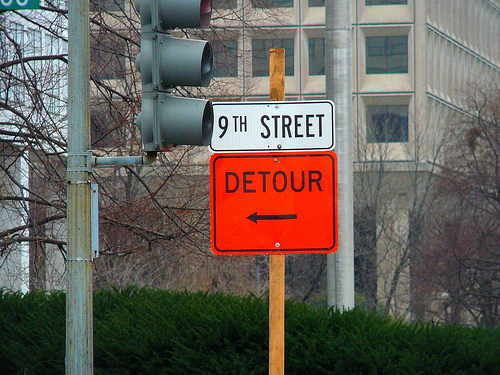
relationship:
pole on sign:
[267, 47, 284, 374] [208, 97, 335, 152]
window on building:
[366, 104, 408, 143] [87, 0, 499, 323]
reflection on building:
[365, 36, 405, 74] [220, 9, 492, 325]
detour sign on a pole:
[209, 150, 339, 255] [267, 47, 284, 374]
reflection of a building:
[365, 36, 405, 74] [15, 1, 475, 318]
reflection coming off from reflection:
[365, 36, 406, 73] [365, 36, 405, 74]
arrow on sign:
[245, 210, 301, 224] [204, 151, 342, 255]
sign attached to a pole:
[209, 99, 339, 155] [264, 40, 301, 375]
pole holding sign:
[267, 47, 284, 374] [208, 96, 339, 259]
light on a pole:
[68, 137, 131, 290] [54, 1, 97, 371]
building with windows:
[366, 39, 417, 94] [360, 0, 416, 149]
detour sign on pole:
[209, 150, 339, 255] [264, 42, 296, 356]